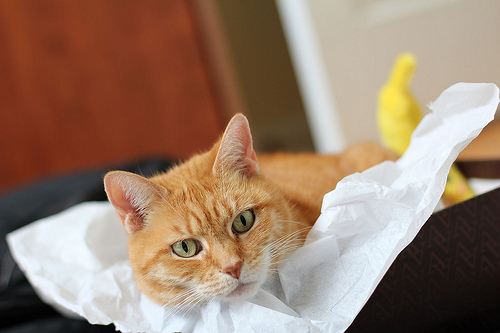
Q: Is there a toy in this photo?
A: Yes, there is a toy.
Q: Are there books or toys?
A: Yes, there is a toy.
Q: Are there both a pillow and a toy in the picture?
A: No, there is a toy but no pillows.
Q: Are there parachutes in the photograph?
A: No, there are no parachutes.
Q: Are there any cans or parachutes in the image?
A: No, there are no parachutes or cans.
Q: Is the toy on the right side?
A: Yes, the toy is on the right of the image.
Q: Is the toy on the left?
A: No, the toy is on the right of the image.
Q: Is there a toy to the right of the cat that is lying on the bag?
A: Yes, there is a toy to the right of the cat.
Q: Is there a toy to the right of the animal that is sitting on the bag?
A: Yes, there is a toy to the right of the cat.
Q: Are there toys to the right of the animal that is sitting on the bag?
A: Yes, there is a toy to the right of the cat.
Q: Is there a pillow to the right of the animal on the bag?
A: No, there is a toy to the right of the cat.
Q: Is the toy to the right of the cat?
A: Yes, the toy is to the right of the cat.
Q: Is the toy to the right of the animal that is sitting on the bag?
A: Yes, the toy is to the right of the cat.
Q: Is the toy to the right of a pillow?
A: No, the toy is to the right of the cat.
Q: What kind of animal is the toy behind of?
A: The toy is behind the cat.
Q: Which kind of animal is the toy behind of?
A: The toy is behind the cat.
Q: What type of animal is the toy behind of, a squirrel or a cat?
A: The toy is behind a cat.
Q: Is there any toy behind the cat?
A: Yes, there is a toy behind the cat.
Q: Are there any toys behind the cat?
A: Yes, there is a toy behind the cat.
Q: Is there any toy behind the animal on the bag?
A: Yes, there is a toy behind the cat.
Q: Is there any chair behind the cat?
A: No, there is a toy behind the cat.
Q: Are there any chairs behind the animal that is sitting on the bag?
A: No, there is a toy behind the cat.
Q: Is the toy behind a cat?
A: Yes, the toy is behind a cat.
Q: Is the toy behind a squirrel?
A: No, the toy is behind a cat.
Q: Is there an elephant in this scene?
A: No, there are no elephants.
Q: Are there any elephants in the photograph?
A: No, there are no elephants.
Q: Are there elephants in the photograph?
A: No, there are no elephants.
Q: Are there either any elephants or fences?
A: No, there are no elephants or fences.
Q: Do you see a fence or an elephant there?
A: No, there are no elephants or fences.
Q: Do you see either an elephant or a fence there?
A: No, there are no elephants or fences.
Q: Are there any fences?
A: No, there are no fences.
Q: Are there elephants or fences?
A: No, there are no fences or elephants.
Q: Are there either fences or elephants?
A: No, there are no fences or elephants.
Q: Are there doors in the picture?
A: Yes, there is a door.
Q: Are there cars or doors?
A: Yes, there is a door.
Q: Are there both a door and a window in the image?
A: No, there is a door but no windows.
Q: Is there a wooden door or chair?
A: Yes, there is a wood door.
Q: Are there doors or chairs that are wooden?
A: Yes, the door is wooden.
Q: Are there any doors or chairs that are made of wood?
A: Yes, the door is made of wood.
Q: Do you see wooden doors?
A: Yes, there is a wood door.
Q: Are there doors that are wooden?
A: Yes, there is a door that is wooden.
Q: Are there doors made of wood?
A: Yes, there is a door that is made of wood.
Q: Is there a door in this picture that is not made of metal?
A: Yes, there is a door that is made of wood.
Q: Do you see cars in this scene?
A: No, there are no cars.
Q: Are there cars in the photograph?
A: No, there are no cars.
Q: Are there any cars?
A: No, there are no cars.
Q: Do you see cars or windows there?
A: No, there are no cars or windows.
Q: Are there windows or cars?
A: No, there are no cars or windows.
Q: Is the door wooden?
A: Yes, the door is wooden.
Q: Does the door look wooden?
A: Yes, the door is wooden.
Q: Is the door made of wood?
A: Yes, the door is made of wood.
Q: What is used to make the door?
A: The door is made of wood.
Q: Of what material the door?
A: The door is made of wood.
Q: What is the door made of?
A: The door is made of wood.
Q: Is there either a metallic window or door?
A: No, there is a door but it is wooden.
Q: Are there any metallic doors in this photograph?
A: No, there is a door but it is wooden.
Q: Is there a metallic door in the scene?
A: No, there is a door but it is wooden.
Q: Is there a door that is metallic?
A: No, there is a door but it is wooden.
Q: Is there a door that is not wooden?
A: No, there is a door but it is wooden.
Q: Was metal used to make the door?
A: No, the door is made of wood.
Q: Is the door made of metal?
A: No, the door is made of wood.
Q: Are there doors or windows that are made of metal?
A: No, there is a door but it is made of wood.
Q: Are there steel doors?
A: No, there is a door but it is made of wood.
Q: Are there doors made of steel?
A: No, there is a door but it is made of wood.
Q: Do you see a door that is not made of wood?
A: No, there is a door but it is made of wood.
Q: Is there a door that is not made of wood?
A: No, there is a door but it is made of wood.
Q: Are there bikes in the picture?
A: No, there are no bikes.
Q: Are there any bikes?
A: No, there are no bikes.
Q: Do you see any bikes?
A: No, there are no bikes.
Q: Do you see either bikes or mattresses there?
A: No, there are no bikes or mattresses.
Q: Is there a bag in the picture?
A: Yes, there is a bag.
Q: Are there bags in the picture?
A: Yes, there is a bag.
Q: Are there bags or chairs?
A: Yes, there is a bag.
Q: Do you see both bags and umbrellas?
A: No, there is a bag but no umbrellas.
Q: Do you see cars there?
A: No, there are no cars.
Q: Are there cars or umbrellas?
A: No, there are no cars or umbrellas.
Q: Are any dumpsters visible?
A: No, there are no dumpsters.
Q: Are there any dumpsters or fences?
A: No, there are no dumpsters or fences.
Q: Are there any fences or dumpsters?
A: No, there are no dumpsters or fences.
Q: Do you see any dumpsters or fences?
A: No, there are no dumpsters or fences.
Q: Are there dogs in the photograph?
A: No, there are no dogs.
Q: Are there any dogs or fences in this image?
A: No, there are no dogs or fences.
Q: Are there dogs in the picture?
A: No, there are no dogs.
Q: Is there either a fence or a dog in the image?
A: No, there are no dogs or fences.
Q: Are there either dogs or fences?
A: No, there are no dogs or fences.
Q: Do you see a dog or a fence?
A: No, there are no dogs or fences.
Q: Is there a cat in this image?
A: Yes, there is a cat.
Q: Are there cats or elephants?
A: Yes, there is a cat.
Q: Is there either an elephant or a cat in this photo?
A: Yes, there is a cat.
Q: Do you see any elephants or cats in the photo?
A: Yes, there is a cat.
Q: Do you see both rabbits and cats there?
A: No, there is a cat but no rabbits.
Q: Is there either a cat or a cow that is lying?
A: Yes, the cat is lying.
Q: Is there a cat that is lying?
A: Yes, there is a cat that is lying.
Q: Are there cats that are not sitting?
A: Yes, there is a cat that is lying.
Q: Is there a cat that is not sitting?
A: Yes, there is a cat that is lying.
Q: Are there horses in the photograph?
A: No, there are no horses.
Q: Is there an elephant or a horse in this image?
A: No, there are no horses or elephants.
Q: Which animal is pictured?
A: The animal is a cat.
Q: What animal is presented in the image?
A: The animal is a cat.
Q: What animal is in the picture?
A: The animal is a cat.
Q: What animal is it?
A: The animal is a cat.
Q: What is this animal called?
A: This is a cat.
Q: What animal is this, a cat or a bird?
A: This is a cat.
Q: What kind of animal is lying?
A: The animal is a cat.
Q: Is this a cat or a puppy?
A: This is a cat.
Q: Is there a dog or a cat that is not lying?
A: No, there is a cat but it is lying.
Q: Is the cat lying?
A: Yes, the cat is lying.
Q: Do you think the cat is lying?
A: Yes, the cat is lying.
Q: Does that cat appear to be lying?
A: Yes, the cat is lying.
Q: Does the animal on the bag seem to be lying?
A: Yes, the cat is lying.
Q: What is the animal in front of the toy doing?
A: The cat is lying.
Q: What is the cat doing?
A: The cat is lying.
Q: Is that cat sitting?
A: No, the cat is lying.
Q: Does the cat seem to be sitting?
A: No, the cat is lying.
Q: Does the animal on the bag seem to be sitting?
A: No, the cat is lying.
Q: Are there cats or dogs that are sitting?
A: No, there is a cat but it is lying.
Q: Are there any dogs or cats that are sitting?
A: No, there is a cat but it is lying.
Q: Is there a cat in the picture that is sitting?
A: No, there is a cat but it is lying.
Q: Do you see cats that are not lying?
A: No, there is a cat but it is lying.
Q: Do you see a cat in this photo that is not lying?
A: No, there is a cat but it is lying.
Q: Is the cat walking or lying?
A: The cat is lying.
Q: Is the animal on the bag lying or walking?
A: The cat is lying.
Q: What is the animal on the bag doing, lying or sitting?
A: The cat is lying.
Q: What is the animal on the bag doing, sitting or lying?
A: The cat is lying.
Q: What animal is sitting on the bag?
A: The animal is a cat.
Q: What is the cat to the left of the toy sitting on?
A: The cat is sitting on the bag.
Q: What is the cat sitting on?
A: The cat is sitting on the bag.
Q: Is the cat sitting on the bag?
A: Yes, the cat is sitting on the bag.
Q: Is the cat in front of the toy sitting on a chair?
A: No, the cat is sitting on the bag.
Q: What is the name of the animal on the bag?
A: The animal is a cat.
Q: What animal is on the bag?
A: The animal is a cat.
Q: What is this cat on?
A: The cat is on the bag.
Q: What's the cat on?
A: The cat is on the bag.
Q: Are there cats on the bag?
A: Yes, there is a cat on the bag.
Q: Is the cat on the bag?
A: Yes, the cat is on the bag.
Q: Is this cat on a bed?
A: No, the cat is on the bag.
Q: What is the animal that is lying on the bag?
A: The animal is a cat.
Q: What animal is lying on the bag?
A: The animal is a cat.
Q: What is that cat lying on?
A: The cat is lying on the bag.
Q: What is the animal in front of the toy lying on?
A: The cat is lying on the bag.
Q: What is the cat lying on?
A: The cat is lying on the bag.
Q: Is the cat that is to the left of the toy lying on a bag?
A: Yes, the cat is lying on a bag.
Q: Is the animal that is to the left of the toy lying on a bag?
A: Yes, the cat is lying on a bag.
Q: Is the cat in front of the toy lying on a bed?
A: No, the cat is lying on a bag.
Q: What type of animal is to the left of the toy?
A: The animal is a cat.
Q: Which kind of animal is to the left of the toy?
A: The animal is a cat.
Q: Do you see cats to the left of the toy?
A: Yes, there is a cat to the left of the toy.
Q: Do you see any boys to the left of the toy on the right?
A: No, there is a cat to the left of the toy.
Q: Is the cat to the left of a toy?
A: Yes, the cat is to the left of a toy.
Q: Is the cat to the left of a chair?
A: No, the cat is to the left of a toy.